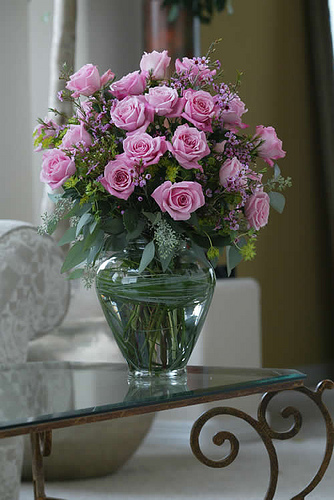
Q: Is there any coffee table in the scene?
A: Yes, there is a coffee table.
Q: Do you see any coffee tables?
A: Yes, there is a coffee table.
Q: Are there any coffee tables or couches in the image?
A: Yes, there is a coffee table.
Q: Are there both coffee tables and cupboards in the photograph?
A: No, there is a coffee table but no cupboards.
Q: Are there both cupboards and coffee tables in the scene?
A: No, there is a coffee table but no cupboards.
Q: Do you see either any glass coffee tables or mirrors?
A: Yes, there is a glass coffee table.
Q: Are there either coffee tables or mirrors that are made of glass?
A: Yes, the coffee table is made of glass.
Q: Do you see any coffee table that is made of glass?
A: Yes, there is a coffee table that is made of glass.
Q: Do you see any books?
A: No, there are no books.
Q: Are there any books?
A: No, there are no books.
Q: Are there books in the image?
A: No, there are no books.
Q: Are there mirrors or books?
A: No, there are no books or mirrors.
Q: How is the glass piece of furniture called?
A: The piece of furniture is a coffee table.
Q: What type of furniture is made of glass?
A: The furniture is a coffee table.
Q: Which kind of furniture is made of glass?
A: The furniture is a coffee table.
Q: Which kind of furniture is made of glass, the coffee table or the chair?
A: The coffee table is made of glass.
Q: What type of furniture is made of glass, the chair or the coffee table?
A: The coffee table is made of glass.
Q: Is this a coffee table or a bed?
A: This is a coffee table.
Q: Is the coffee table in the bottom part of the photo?
A: Yes, the coffee table is in the bottom of the image.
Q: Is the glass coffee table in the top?
A: No, the coffee table is in the bottom of the image.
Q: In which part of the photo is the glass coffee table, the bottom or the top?
A: The coffee table is in the bottom of the image.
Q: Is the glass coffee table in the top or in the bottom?
A: The coffee table is in the bottom of the image.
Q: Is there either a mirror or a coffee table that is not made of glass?
A: No, there is a coffee table but it is made of glass.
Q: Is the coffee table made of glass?
A: Yes, the coffee table is made of glass.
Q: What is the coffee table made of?
A: The coffee table is made of glass.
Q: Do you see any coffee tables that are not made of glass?
A: No, there is a coffee table but it is made of glass.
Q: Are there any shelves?
A: No, there are no shelves.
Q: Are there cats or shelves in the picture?
A: No, there are no shelves or cats.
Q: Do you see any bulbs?
A: No, there are no bulbs.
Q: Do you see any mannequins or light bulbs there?
A: No, there are no light bulbs or mannequins.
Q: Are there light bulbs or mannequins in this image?
A: No, there are no light bulbs or mannequins.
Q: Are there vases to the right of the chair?
A: Yes, there is a vase to the right of the chair.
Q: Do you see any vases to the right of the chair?
A: Yes, there is a vase to the right of the chair.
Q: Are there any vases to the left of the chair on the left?
A: No, the vase is to the right of the chair.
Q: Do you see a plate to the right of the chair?
A: No, there is a vase to the right of the chair.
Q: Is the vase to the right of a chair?
A: Yes, the vase is to the right of a chair.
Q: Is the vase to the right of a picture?
A: No, the vase is to the right of a chair.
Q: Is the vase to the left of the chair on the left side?
A: No, the vase is to the right of the chair.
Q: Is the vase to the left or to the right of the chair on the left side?
A: The vase is to the right of the chair.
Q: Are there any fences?
A: No, there are no fences.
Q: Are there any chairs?
A: Yes, there is a chair.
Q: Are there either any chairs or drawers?
A: Yes, there is a chair.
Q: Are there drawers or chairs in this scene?
A: Yes, there is a chair.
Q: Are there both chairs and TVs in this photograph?
A: No, there is a chair but no televisions.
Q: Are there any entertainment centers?
A: No, there are no entertainment centers.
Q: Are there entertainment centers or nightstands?
A: No, there are no entertainment centers or nightstands.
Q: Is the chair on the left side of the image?
A: Yes, the chair is on the left of the image.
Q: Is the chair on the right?
A: No, the chair is on the left of the image.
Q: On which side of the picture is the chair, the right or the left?
A: The chair is on the left of the image.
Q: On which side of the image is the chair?
A: The chair is on the left of the image.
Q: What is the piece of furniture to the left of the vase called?
A: The piece of furniture is a chair.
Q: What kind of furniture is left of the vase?
A: The piece of furniture is a chair.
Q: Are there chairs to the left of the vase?
A: Yes, there is a chair to the left of the vase.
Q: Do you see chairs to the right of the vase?
A: No, the chair is to the left of the vase.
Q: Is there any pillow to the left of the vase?
A: No, there is a chair to the left of the vase.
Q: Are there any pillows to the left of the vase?
A: No, there is a chair to the left of the vase.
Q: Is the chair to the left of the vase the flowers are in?
A: Yes, the chair is to the left of the vase.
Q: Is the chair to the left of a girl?
A: No, the chair is to the left of the vase.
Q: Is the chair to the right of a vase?
A: No, the chair is to the left of a vase.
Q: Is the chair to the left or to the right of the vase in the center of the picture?
A: The chair is to the left of the vase.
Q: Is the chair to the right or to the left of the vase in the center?
A: The chair is to the left of the vase.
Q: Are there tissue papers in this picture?
A: No, there are no tissue papers.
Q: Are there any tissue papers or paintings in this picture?
A: No, there are no tissue papers or paintings.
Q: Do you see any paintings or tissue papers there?
A: No, there are no tissue papers or paintings.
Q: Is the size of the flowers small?
A: Yes, the flowers are small.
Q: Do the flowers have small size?
A: Yes, the flowers are small.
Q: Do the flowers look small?
A: Yes, the flowers are small.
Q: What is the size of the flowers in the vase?
A: The flowers are small.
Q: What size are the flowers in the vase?
A: The flowers are small.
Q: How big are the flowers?
A: The flowers are small.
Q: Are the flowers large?
A: No, the flowers are small.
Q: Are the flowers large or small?
A: The flowers are small.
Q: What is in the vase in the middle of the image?
A: The flowers are in the vase.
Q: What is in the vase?
A: The flowers are in the vase.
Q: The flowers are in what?
A: The flowers are in the vase.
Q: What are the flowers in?
A: The flowers are in the vase.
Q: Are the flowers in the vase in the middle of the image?
A: Yes, the flowers are in the vase.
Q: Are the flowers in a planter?
A: No, the flowers are in the vase.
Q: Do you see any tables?
A: Yes, there is a table.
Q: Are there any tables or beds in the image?
A: Yes, there is a table.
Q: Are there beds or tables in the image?
A: Yes, there is a table.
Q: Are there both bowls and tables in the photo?
A: No, there is a table but no bowls.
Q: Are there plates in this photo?
A: No, there are no plates.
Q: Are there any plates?
A: No, there are no plates.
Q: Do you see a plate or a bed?
A: No, there are no plates or beds.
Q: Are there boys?
A: No, there are no boys.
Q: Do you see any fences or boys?
A: No, there are no boys or fences.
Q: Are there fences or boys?
A: No, there are no boys or fences.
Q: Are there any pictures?
A: No, there are no pictures.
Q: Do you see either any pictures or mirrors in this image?
A: No, there are no pictures or mirrors.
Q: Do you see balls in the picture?
A: No, there are no balls.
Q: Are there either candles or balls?
A: No, there are no balls or candles.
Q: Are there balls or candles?
A: No, there are no balls or candles.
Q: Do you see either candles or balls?
A: No, there are no balls or candles.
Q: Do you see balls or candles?
A: No, there are no balls or candles.